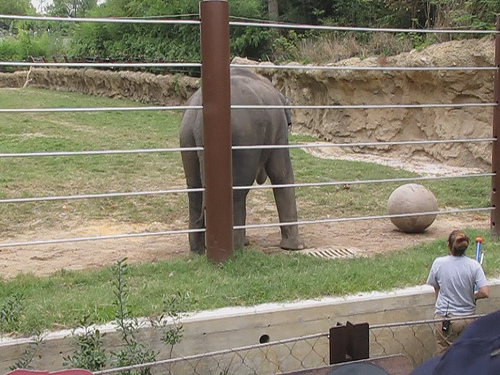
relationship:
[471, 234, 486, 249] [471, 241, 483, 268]
orange ball on blue pole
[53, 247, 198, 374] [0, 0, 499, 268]
plant outside of fence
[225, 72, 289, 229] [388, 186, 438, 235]
elephant played with ball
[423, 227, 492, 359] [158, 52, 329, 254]
human watching elephant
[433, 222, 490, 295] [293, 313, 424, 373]
human kept safe by gate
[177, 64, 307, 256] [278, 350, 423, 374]
elephant standing near gate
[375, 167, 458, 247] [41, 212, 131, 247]
ball in dirt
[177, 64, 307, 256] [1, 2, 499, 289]
elephant in enclosure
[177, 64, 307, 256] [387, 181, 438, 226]
elephant near ball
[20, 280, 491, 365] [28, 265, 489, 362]
cement on wall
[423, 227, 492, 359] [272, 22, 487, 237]
human by fence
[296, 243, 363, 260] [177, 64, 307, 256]
grate by elephant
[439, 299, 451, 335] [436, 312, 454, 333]
radio in pocket